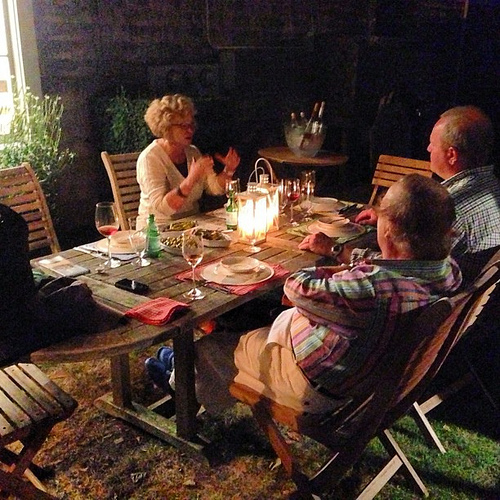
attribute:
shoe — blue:
[143, 355, 171, 398]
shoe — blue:
[158, 341, 179, 372]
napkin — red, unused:
[120, 290, 192, 333]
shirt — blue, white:
[437, 162, 499, 267]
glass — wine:
[238, 175, 296, 239]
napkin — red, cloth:
[123, 297, 188, 336]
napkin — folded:
[123, 295, 188, 323]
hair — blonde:
[146, 95, 198, 125]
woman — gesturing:
[134, 92, 241, 230]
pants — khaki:
[169, 314, 350, 421]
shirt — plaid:
[283, 255, 463, 402]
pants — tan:
[169, 306, 344, 417]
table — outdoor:
[29, 180, 380, 462]